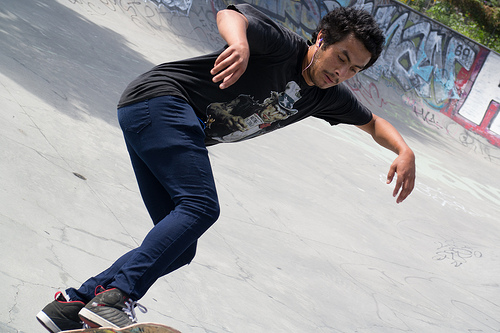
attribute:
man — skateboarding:
[38, 4, 416, 332]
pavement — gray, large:
[3, 0, 496, 332]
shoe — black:
[79, 289, 135, 332]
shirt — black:
[118, 3, 371, 145]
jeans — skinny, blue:
[66, 97, 219, 310]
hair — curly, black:
[313, 6, 384, 72]